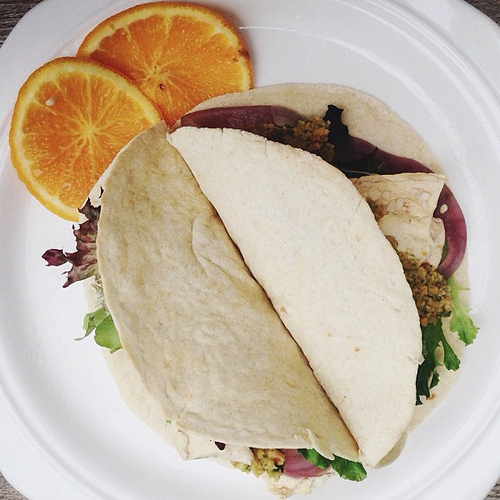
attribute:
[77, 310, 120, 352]
lettuce — green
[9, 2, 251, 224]
oranges — sliced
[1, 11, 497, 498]
plate — white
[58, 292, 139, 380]
lettuce — green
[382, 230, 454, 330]
meat — brown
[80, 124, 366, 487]
tortilla — white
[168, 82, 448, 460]
tortilla — white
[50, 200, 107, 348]
lettuce — purple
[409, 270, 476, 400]
lettuce — green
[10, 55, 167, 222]
orange — round